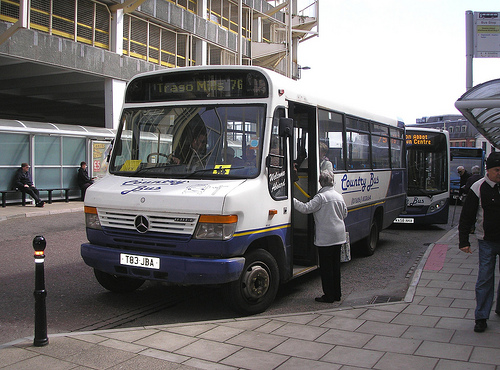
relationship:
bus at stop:
[79, 64, 407, 315] [456, 7, 498, 156]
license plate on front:
[117, 252, 164, 268] [83, 67, 256, 308]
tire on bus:
[223, 249, 279, 315] [79, 64, 407, 315]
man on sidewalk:
[454, 149, 499, 336] [419, 275, 476, 368]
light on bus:
[83, 212, 101, 229] [79, 64, 407, 315]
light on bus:
[195, 222, 230, 239] [79, 64, 407, 315]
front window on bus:
[110, 100, 265, 181] [79, 64, 407, 315]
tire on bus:
[229, 250, 288, 313] [79, 64, 407, 315]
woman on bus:
[294, 171, 353, 304] [79, 64, 407, 315]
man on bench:
[16, 160, 41, 202] [42, 185, 69, 191]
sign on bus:
[406, 132, 433, 144] [389, 121, 453, 228]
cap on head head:
[484, 147, 499, 168] [481, 149, 498, 183]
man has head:
[454, 149, 499, 336] [481, 149, 498, 183]